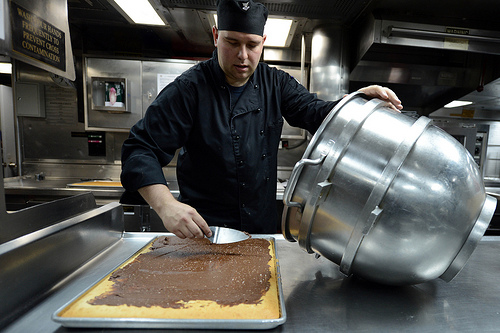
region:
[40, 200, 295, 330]
cake is being frosted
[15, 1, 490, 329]
an industrial kitchen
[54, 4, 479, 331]
a man in a kitchen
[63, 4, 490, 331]
a man spreads frosting onto a pan of cake or cookies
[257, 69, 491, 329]
a large metal bowl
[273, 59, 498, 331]
a large metal bowl filled with chocolate frosting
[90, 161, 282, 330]
the frosting is chocolate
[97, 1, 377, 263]
the man wears a black outfit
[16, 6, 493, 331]
the kitchen is all stainless steel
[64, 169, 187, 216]
a second pan of food awaits frosting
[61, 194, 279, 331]
a cake being worked on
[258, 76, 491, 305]
metal food bin is silver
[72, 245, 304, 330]
Silver pan with desert in it.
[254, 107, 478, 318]
Large silver mixing bowl.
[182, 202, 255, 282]
Small silver spatula in hand.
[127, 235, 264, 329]
Chocolate sauce on cookie.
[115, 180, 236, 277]
A hand holding a spatula.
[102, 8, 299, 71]
Black hat with a silver pin.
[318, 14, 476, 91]
Silver and black vent system.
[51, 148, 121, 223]
Desert cooling on pan.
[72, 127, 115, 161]
A red and black object.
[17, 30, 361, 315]
A chef making a desert.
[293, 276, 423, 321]
table is steel and metal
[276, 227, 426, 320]
table is steel and metal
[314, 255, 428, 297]
table is steel and metal